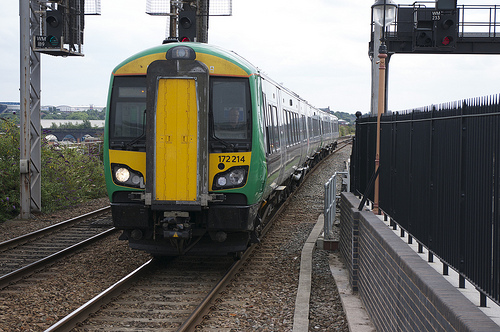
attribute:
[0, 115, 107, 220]
bushes — green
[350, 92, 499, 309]
fence — tall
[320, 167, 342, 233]
railing — large, silve, sort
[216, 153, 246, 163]
number — large, black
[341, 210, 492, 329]
wall — bricked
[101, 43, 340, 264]
train — green , short , yellow 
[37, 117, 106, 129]
roof — large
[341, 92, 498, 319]
fence — black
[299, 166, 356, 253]
gate — silver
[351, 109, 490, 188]
iron fence — black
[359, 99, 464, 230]
fence — iron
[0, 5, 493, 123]
sky — sunny